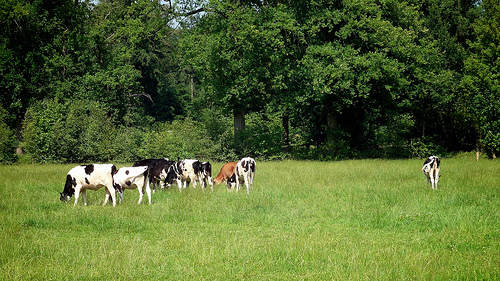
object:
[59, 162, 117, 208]
cow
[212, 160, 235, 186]
cow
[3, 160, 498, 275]
grass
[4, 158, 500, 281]
field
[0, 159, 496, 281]
green grass field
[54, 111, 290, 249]
eating green grass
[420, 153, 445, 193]
cow by itself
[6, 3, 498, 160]
forested area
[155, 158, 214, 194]
black and white cow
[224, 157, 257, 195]
black and white cow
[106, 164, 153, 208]
black and white cow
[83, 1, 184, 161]
tall trees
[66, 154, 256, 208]
group of cows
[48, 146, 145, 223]
in the foreground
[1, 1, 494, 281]
in the daytime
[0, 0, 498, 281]
taken outdoors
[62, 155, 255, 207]
six cows eating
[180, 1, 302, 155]
big leafy tree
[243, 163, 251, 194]
cow's rear legs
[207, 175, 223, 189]
brown cow's head